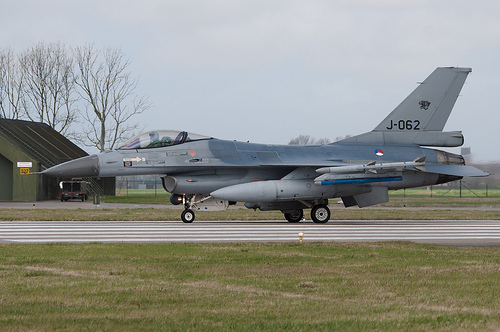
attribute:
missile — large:
[208, 174, 369, 211]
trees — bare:
[2, 38, 134, 208]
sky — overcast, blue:
[2, 4, 494, 176]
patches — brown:
[3, 240, 494, 325]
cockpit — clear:
[115, 128, 213, 151]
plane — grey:
[41, 50, 476, 219]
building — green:
[7, 130, 43, 198]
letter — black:
[389, 119, 395, 137]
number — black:
[401, 120, 423, 132]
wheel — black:
[312, 209, 335, 228]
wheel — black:
[179, 209, 199, 224]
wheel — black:
[290, 210, 302, 220]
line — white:
[62, 227, 71, 229]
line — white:
[124, 232, 139, 237]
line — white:
[163, 228, 169, 229]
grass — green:
[51, 211, 173, 219]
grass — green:
[383, 209, 493, 221]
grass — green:
[23, 252, 499, 314]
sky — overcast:
[146, 9, 443, 64]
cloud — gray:
[355, 27, 433, 56]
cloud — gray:
[94, 11, 153, 33]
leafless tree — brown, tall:
[63, 43, 151, 153]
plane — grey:
[36, 43, 490, 254]